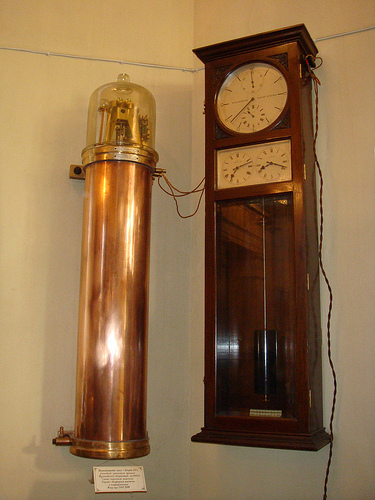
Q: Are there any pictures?
A: No, there are no pictures.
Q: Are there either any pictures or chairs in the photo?
A: No, there are no pictures or chairs.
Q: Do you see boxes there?
A: No, there are no boxes.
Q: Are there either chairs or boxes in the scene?
A: No, there are no boxes or chairs.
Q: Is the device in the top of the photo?
A: Yes, the device is in the top of the image.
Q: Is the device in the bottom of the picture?
A: No, the device is in the top of the image.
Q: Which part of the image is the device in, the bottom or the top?
A: The device is in the top of the image.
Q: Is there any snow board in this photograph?
A: No, there are no snowboards.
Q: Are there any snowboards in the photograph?
A: No, there are no snowboards.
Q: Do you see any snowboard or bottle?
A: No, there are no snowboards or bottles.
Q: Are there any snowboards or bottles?
A: No, there are no snowboards or bottles.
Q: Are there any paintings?
A: No, there are no paintings.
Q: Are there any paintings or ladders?
A: No, there are no paintings or ladders.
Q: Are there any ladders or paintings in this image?
A: No, there are no paintings or ladders.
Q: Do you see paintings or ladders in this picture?
A: No, there are no paintings or ladders.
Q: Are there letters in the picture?
A: Yes, there are letters.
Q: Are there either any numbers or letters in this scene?
A: Yes, there are letters.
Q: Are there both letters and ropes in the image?
A: No, there are letters but no ropes.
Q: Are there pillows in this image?
A: No, there are no pillows.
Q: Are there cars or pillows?
A: No, there are no pillows or cars.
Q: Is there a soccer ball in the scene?
A: No, there are no soccer balls.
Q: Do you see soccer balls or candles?
A: No, there are no soccer balls or candles.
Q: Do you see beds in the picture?
A: No, there are no beds.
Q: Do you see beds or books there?
A: No, there are no beds or books.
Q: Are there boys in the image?
A: No, there are no boys.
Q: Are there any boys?
A: No, there are no boys.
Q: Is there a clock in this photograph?
A: Yes, there is a clock.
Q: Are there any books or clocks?
A: Yes, there is a clock.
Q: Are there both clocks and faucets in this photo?
A: No, there is a clock but no faucets.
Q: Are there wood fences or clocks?
A: Yes, there is a wood clock.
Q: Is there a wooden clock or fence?
A: Yes, there is a wood clock.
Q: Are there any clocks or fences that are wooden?
A: Yes, the clock is wooden.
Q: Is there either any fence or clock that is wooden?
A: Yes, the clock is wooden.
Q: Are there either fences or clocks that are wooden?
A: Yes, the clock is wooden.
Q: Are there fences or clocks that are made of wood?
A: Yes, the clock is made of wood.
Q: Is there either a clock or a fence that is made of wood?
A: Yes, the clock is made of wood.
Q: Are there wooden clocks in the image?
A: Yes, there is a wood clock.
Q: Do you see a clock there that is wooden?
A: Yes, there is a clock that is wooden.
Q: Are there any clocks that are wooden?
A: Yes, there is a clock that is wooden.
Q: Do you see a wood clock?
A: Yes, there is a clock that is made of wood.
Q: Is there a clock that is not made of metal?
A: Yes, there is a clock that is made of wood.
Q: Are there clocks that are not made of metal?
A: Yes, there is a clock that is made of wood.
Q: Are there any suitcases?
A: No, there are no suitcases.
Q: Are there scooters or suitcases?
A: No, there are no suitcases or scooters.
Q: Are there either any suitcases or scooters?
A: No, there are no suitcases or scooters.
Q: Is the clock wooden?
A: Yes, the clock is wooden.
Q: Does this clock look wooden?
A: Yes, the clock is wooden.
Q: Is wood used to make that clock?
A: Yes, the clock is made of wood.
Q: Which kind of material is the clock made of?
A: The clock is made of wood.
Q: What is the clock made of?
A: The clock is made of wood.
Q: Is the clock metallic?
A: No, the clock is wooden.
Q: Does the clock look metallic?
A: No, the clock is wooden.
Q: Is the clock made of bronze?
A: No, the clock is made of wood.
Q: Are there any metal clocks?
A: No, there is a clock but it is made of wood.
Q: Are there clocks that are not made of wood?
A: No, there is a clock but it is made of wood.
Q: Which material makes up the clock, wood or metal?
A: The clock is made of wood.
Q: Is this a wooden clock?
A: Yes, this is a wooden clock.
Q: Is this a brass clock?
A: No, this is a wooden clock.